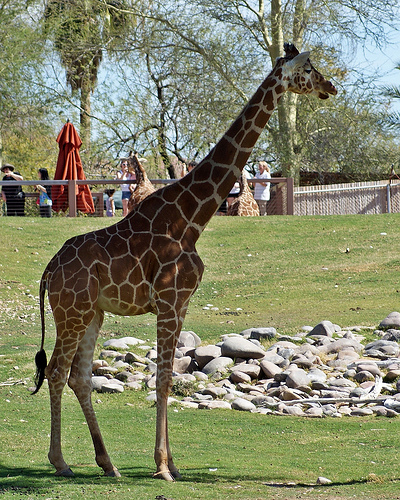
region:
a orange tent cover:
[47, 112, 86, 206]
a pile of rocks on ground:
[89, 307, 399, 448]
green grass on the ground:
[23, 430, 269, 489]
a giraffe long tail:
[15, 245, 61, 403]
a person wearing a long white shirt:
[243, 152, 279, 220]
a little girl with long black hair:
[27, 165, 51, 201]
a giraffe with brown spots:
[116, 192, 197, 303]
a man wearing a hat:
[0, 142, 21, 178]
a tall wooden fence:
[271, 171, 399, 224]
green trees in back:
[2, 12, 182, 120]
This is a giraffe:
[49, 177, 242, 456]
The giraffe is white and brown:
[50, 133, 167, 362]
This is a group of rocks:
[210, 318, 348, 446]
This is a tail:
[27, 298, 69, 380]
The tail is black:
[21, 334, 75, 427]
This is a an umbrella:
[45, 138, 93, 190]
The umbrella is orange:
[42, 136, 112, 226]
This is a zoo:
[110, 168, 388, 402]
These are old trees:
[295, 131, 333, 165]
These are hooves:
[46, 429, 174, 493]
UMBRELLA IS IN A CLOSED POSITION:
[40, 115, 86, 226]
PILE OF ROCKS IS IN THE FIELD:
[72, 331, 382, 426]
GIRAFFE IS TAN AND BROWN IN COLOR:
[50, 34, 360, 470]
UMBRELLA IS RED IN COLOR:
[48, 120, 99, 206]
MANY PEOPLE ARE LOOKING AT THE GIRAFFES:
[3, 155, 152, 205]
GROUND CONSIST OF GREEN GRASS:
[3, 384, 392, 489]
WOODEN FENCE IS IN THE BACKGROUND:
[276, 172, 397, 210]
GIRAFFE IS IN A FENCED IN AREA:
[2, 172, 301, 219]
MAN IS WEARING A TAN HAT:
[0, 163, 34, 214]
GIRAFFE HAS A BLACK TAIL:
[31, 343, 56, 391]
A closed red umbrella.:
[53, 117, 96, 211]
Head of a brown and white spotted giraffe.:
[275, 41, 337, 102]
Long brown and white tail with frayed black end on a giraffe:
[30, 277, 48, 396]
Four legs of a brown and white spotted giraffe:
[40, 311, 184, 482]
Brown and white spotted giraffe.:
[32, 43, 339, 481]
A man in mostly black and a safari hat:
[2, 160, 26, 216]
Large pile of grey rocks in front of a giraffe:
[187, 311, 399, 417]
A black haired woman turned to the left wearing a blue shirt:
[32, 166, 54, 215]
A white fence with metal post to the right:
[294, 178, 399, 212]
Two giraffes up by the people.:
[127, 151, 261, 217]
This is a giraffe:
[27, 36, 355, 496]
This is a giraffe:
[105, 117, 173, 223]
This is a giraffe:
[225, 160, 261, 234]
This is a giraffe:
[166, 155, 195, 192]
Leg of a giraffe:
[67, 317, 127, 491]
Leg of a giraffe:
[34, 299, 88, 493]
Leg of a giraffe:
[138, 294, 172, 482]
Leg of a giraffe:
[166, 297, 195, 481]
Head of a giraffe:
[270, 39, 346, 114]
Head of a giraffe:
[123, 143, 150, 169]